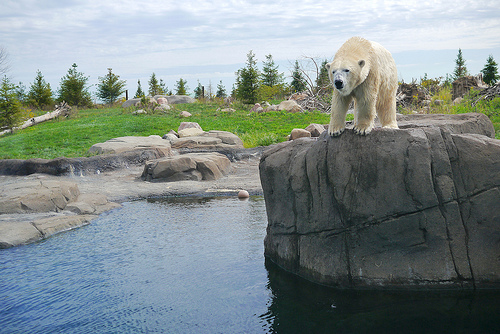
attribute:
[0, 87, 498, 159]
grass — green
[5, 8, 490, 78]
sky — gray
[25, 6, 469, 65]
clouds — white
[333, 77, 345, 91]
nose — black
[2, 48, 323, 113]
trees — coniferous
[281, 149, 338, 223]
rock — manufactured